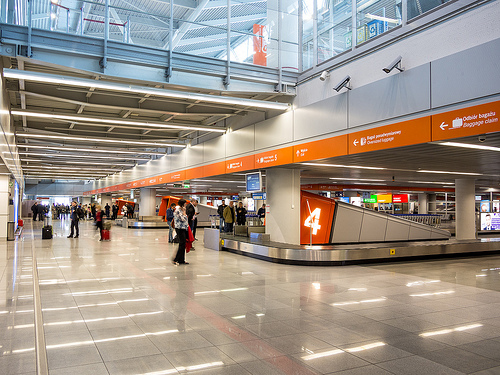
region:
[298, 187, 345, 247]
Orange sign that says 4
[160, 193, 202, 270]
A woman standing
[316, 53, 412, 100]
Video cameras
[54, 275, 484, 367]
Reflections of lights on the floor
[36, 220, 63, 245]
Bags sitting in the background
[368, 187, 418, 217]
Bright signs in the distance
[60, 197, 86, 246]
Person standing legs apart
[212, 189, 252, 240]
Group of men standing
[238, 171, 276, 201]
A large television screen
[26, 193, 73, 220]
Lots of people in the background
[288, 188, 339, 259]
orange sign with the number 4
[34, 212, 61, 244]
black suitcase with a handle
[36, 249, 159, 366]
a tile floor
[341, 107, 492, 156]
signs with arrows pointing left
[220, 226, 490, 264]
baggage carousel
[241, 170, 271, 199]
information screen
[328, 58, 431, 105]
two security cameras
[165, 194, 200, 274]
person with light top and dark pants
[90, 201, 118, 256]
person with a red suitcase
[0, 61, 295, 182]
light fixtures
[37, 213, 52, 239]
black suitcase with handle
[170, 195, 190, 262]
person wearing black and white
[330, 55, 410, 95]
security cameras on wall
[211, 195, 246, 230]
group of people standing together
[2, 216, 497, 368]
shiny tan tiled floor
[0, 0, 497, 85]
large window panels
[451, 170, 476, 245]
round white pillar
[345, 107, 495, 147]
directions posted on orange background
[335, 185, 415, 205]
blue, green, yellow, and red signs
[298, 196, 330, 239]
large number four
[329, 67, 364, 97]
a security camera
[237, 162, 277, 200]
a monitor hanging from the wall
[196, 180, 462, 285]
a baggage claim area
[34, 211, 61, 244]
a dark colored suitcase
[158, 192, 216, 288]
a woman talking on the phone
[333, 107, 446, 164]
directions to the baggae claim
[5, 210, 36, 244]
a silver trash can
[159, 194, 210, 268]
a woman with a red coat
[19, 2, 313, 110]
a glass wall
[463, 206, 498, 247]
a television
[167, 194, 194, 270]
A woman wearing a white and blue shirt.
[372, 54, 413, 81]
Security camera.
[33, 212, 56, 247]
A black suit case with handle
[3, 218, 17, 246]
A mall trash can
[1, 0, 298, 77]
A glass window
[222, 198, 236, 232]
Man in olive green jacket.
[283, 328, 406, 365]
Reflection of lights shinning on the floor.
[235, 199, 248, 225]
Woman in black coat waiting for luggage.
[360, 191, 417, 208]
blue, yellow and red signs.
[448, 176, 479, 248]
White Pillar